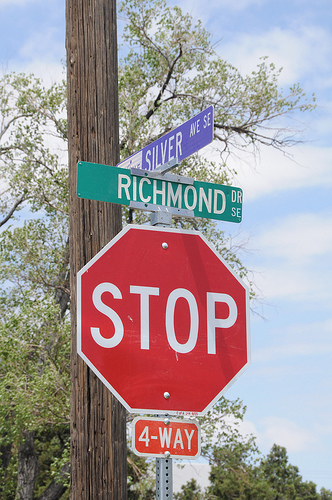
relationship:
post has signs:
[151, 465, 188, 499] [91, 119, 270, 478]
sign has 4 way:
[131, 420, 200, 456] [139, 426, 191, 449]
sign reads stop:
[51, 227, 267, 404] [95, 281, 234, 358]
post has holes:
[151, 465, 188, 499] [165, 469, 170, 487]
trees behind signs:
[7, 241, 69, 443] [91, 119, 270, 478]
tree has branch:
[130, 35, 226, 105] [223, 115, 272, 145]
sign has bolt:
[51, 227, 267, 404] [154, 232, 175, 259]